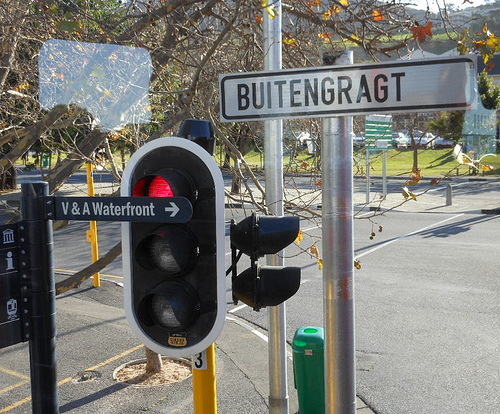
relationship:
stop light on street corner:
[111, 133, 234, 359] [1, 272, 383, 413]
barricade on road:
[1, 182, 500, 213] [1, 171, 499, 327]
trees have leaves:
[1, 0, 450, 188] [240, 2, 499, 58]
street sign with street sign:
[54, 196, 193, 224] [54, 196, 193, 224]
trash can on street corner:
[289, 324, 328, 413] [1, 272, 383, 413]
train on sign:
[5, 298, 20, 321] [1, 221, 41, 352]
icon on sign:
[2, 251, 17, 275] [1, 221, 41, 352]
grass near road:
[3, 154, 499, 176] [1, 171, 499, 327]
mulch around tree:
[410, 167, 424, 176] [393, 109, 462, 172]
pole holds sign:
[320, 50, 358, 414] [203, 56, 483, 123]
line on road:
[223, 212, 468, 317] [1, 171, 499, 327]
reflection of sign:
[40, 34, 166, 138] [203, 56, 483, 123]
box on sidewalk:
[289, 324, 328, 413] [1, 272, 383, 413]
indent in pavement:
[66, 363, 103, 390] [1, 272, 383, 413]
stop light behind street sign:
[111, 133, 234, 359] [54, 196, 193, 224]